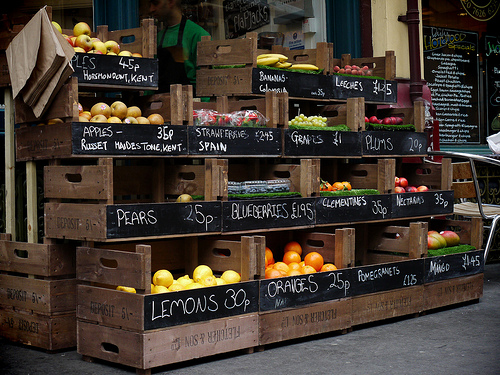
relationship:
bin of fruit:
[76, 236, 258, 370] [265, 241, 338, 279]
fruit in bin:
[265, 241, 338, 279] [246, 222, 362, 338]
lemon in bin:
[152, 267, 174, 288] [72, 236, 259, 373]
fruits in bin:
[117, 264, 242, 294] [72, 236, 259, 373]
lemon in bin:
[220, 267, 242, 287] [72, 236, 259, 373]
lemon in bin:
[114, 281, 136, 297] [72, 236, 259, 373]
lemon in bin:
[150, 283, 170, 295] [72, 236, 259, 373]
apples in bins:
[57, 19, 167, 129] [41, 1, 198, 131]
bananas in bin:
[251, 46, 319, 74] [194, 36, 328, 96]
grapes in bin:
[290, 110, 325, 125] [275, 121, 365, 159]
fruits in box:
[337, 240, 419, 312] [325, 217, 432, 329]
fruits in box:
[37, 14, 473, 315] [69, 235, 258, 370]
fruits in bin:
[37, 14, 473, 315] [206, 222, 352, 315]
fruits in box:
[37, 14, 473, 315] [328, 219, 427, 331]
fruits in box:
[37, 14, 473, 315] [402, 216, 485, 315]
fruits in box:
[37, 14, 473, 315] [366, 152, 456, 220]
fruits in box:
[37, 14, 473, 315] [282, 157, 392, 226]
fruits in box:
[37, 14, 473, 315] [216, 156, 316, 235]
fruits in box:
[37, 14, 473, 315] [45, 152, 220, 243]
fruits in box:
[37, 14, 473, 315] [7, 75, 184, 163]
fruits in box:
[37, 14, 473, 315] [162, 87, 280, 162]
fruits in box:
[37, 14, 473, 315] [248, 93, 362, 157]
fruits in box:
[37, 14, 473, 315] [343, 96, 430, 153]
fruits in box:
[37, 14, 473, 315] [304, 42, 399, 100]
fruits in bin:
[37, 14, 473, 315] [195, 32, 329, 102]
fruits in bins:
[37, 14, 473, 315] [8, 6, 159, 93]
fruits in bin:
[117, 264, 242, 294] [76, 236, 258, 370]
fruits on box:
[228, 164, 286, 185] [217, 156, 316, 214]